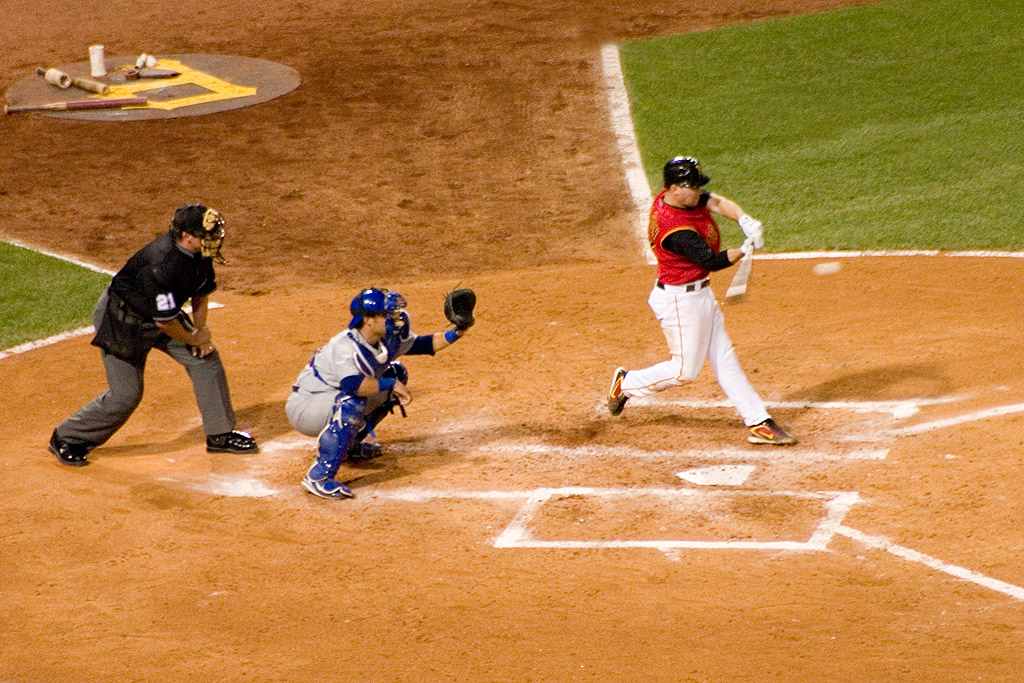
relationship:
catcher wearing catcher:
[286, 286, 480, 477] [285, 286, 477, 502]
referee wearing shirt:
[57, 207, 251, 463] [114, 235, 214, 330]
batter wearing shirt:
[622, 155, 747, 317] [638, 200, 734, 286]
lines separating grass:
[588, 35, 681, 245] [742, 35, 978, 245]